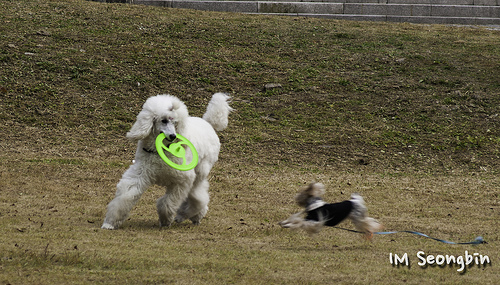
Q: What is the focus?
A: Dogs playing with frisbee.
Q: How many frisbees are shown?
A: 1.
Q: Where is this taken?
A: Park.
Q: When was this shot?
A: Daytime.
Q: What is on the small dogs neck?
A: Leash.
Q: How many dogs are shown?
A: 2.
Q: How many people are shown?
A: 0.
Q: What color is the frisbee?
A: Neon green.